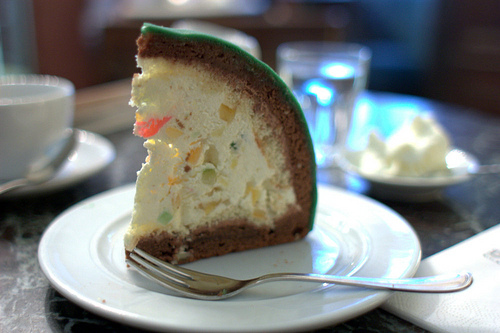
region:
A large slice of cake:
[115, 18, 320, 260]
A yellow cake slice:
[115, 10, 310, 275]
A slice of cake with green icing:
[135, 15, 320, 225]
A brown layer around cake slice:
[161, 221, 293, 256]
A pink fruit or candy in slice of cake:
[130, 91, 185, 151]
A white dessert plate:
[27, 190, 427, 325]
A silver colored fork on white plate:
[115, 241, 495, 326]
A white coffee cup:
[0, 70, 70, 160]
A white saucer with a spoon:
[0, 155, 107, 187]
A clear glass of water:
[282, 30, 362, 162]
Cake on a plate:
[116, 15, 336, 268]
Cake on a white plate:
[125, 17, 322, 264]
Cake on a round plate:
[127, 19, 324, 270]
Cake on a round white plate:
[125, 19, 322, 273]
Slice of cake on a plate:
[120, 16, 321, 271]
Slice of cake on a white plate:
[120, 17, 321, 267]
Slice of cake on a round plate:
[121, 18, 319, 270]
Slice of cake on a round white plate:
[123, 19, 319, 272]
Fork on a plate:
[124, 244, 476, 303]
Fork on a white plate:
[121, 242, 477, 302]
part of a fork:
[437, 275, 451, 301]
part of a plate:
[310, 313, 322, 323]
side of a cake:
[232, 168, 250, 180]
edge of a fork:
[412, 270, 427, 296]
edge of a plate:
[379, 235, 380, 240]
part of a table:
[68, 306, 77, 312]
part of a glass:
[323, 100, 332, 118]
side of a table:
[48, 310, 59, 328]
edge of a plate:
[368, 236, 383, 254]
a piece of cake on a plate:
[22, 17, 476, 319]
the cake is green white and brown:
[84, 41, 323, 273]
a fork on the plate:
[109, 242, 499, 302]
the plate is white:
[43, 228, 368, 329]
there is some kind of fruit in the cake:
[106, 77, 271, 217]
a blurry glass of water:
[282, 31, 387, 164]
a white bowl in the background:
[8, 70, 110, 180]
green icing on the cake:
[137, 23, 274, 60]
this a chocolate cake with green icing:
[132, 25, 245, 64]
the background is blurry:
[274, 7, 489, 51]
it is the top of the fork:
[129, 245, 239, 305]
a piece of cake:
[117, 25, 311, 256]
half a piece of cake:
[118, 27, 319, 253]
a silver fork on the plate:
[127, 245, 477, 303]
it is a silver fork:
[130, 244, 469, 299]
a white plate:
[38, 183, 436, 319]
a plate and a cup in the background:
[0, 67, 112, 192]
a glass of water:
[276, 35, 373, 167]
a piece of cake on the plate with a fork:
[57, 23, 417, 326]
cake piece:
[128, 21, 308, 269]